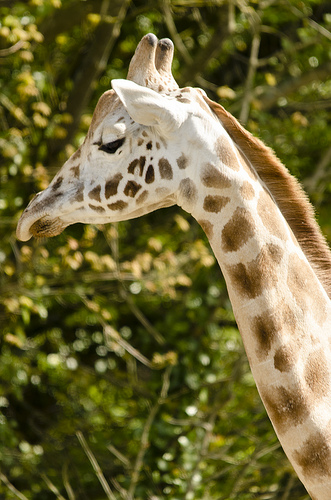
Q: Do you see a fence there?
A: No, there are no fences.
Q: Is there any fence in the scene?
A: No, there are no fences.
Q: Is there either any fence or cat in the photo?
A: No, there are no fences or cats.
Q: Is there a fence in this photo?
A: No, there are no fences.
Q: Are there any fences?
A: No, there are no fences.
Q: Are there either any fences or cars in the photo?
A: No, there are no fences or cars.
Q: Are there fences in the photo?
A: No, there are no fences.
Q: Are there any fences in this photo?
A: No, there are no fences.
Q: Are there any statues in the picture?
A: No, there are no statues.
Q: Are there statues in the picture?
A: No, there are no statues.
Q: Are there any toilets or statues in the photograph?
A: No, there are no statues or toilets.